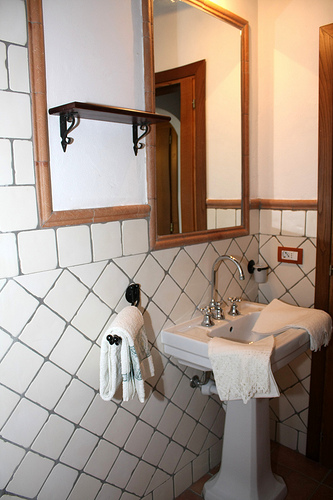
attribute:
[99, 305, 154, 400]
towel — white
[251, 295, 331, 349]
towel — white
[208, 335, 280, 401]
towel — white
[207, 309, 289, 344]
basin — white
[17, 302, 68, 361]
tile — white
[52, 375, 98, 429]
tile — white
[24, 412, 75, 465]
tile — white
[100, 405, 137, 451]
tile — white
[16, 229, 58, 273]
tile — white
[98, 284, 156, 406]
towel — white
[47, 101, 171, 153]
shelf — brown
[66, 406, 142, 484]
tiles — white